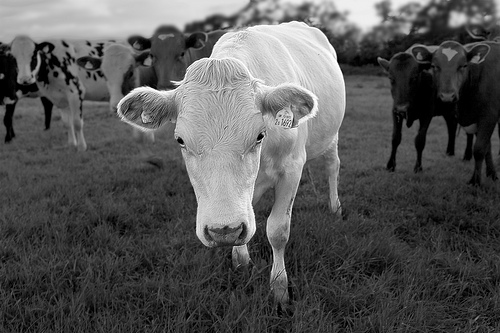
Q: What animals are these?
A: Cows.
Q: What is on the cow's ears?
A: ID tags.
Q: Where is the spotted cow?
A: Background left.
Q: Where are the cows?
A: Pasture.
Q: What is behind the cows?
A: Trees.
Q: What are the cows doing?
A: Watching.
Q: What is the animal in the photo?
A: A cow.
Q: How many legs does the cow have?
A: Four.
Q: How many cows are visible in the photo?
A: Six.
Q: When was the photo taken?
A: During the day.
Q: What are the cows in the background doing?
A: Standing.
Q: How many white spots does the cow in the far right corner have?
A: Three.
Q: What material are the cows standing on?
A: Grass.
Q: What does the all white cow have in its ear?
A: A tag.